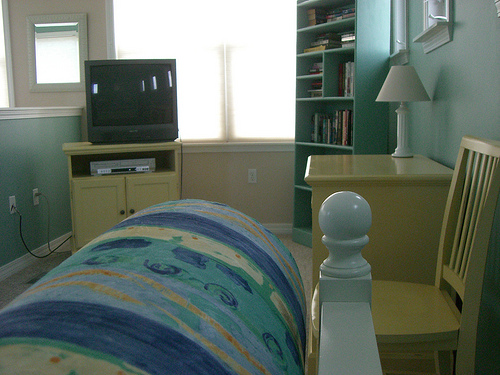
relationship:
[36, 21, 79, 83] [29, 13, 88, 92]
mirror with a frame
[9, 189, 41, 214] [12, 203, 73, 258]
outlets with wires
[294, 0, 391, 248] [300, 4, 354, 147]
bookcase full of books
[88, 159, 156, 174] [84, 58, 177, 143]
dvd player and television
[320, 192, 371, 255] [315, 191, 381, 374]
knob of bed post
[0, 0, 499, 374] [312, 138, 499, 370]
bedroom has chair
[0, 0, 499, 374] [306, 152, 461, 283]
bedroom has dresser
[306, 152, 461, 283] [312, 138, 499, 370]
dresser matches chair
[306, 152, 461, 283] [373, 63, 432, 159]
dresser has a lamp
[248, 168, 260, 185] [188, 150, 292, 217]
electrical outlet on wall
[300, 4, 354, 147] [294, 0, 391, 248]
books on bookcase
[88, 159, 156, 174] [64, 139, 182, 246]
dvd player on stand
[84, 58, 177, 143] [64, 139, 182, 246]
television on stand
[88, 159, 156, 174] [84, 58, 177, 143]
dvd player under television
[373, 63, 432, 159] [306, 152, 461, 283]
lamp on dresser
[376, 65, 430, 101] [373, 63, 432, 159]
lampshade on lamp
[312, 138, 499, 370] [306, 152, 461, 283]
chair next to dresser